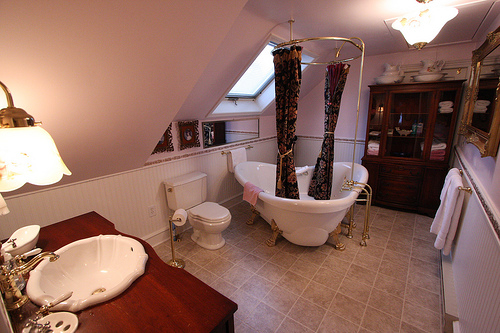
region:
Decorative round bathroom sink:
[20, 228, 156, 310]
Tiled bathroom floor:
[255, 260, 425, 331]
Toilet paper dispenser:
[162, 207, 193, 269]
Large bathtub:
[232, 147, 374, 266]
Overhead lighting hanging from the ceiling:
[379, 4, 469, 54]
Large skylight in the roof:
[217, 34, 299, 111]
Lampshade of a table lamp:
[0, 70, 90, 197]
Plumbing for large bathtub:
[337, 171, 376, 252]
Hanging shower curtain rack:
[260, 29, 386, 69]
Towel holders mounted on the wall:
[217, 143, 260, 159]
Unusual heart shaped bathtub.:
[230, 134, 384, 293]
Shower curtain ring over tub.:
[270, 25, 357, 202]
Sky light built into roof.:
[197, 15, 324, 134]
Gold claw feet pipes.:
[255, 183, 388, 256]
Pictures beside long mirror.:
[146, 112, 286, 159]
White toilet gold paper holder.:
[155, 170, 242, 270]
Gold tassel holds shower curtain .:
[268, 40, 313, 200]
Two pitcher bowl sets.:
[364, 50, 472, 97]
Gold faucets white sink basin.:
[4, 233, 149, 310]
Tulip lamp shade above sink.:
[1, 82, 100, 219]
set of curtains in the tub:
[250, 47, 401, 217]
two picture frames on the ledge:
[135, 128, 195, 163]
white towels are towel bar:
[440, 163, 485, 269]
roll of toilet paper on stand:
[154, 207, 187, 260]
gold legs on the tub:
[242, 211, 352, 256]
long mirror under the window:
[195, 116, 276, 154]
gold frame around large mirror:
[455, 37, 498, 167]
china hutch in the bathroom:
[355, 67, 452, 227]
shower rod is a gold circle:
[271, 18, 392, 72]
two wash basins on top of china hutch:
[373, 57, 452, 90]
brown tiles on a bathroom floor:
[305, 260, 420, 325]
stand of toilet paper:
[165, 205, 190, 265]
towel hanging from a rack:
[430, 160, 470, 240]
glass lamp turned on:
[0, 75, 80, 200]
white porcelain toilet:
[185, 165, 235, 255]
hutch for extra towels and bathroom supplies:
[365, 75, 450, 210]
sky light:
[215, 70, 275, 115]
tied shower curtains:
[265, 70, 350, 195]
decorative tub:
[235, 140, 370, 260]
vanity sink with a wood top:
[5, 210, 171, 325]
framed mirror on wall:
[456, 21, 498, 159]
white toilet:
[163, 166, 235, 249]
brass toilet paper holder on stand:
[166, 205, 189, 269]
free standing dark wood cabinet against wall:
[347, 69, 469, 219]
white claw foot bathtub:
[231, 152, 374, 254]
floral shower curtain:
[270, 44, 309, 199]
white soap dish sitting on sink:
[1, 220, 41, 256]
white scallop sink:
[25, 233, 151, 315]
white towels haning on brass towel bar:
[428, 162, 476, 263]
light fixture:
[0, 78, 72, 193]